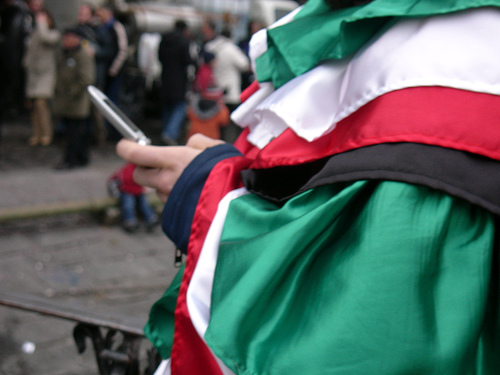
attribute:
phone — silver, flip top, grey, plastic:
[87, 84, 154, 145]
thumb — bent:
[184, 132, 227, 151]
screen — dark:
[103, 97, 140, 133]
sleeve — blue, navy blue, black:
[162, 141, 244, 255]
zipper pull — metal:
[174, 246, 183, 268]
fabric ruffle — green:
[255, 1, 500, 90]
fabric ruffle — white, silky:
[229, 4, 500, 149]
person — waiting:
[108, 159, 160, 235]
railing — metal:
[0, 291, 163, 374]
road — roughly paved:
[1, 218, 187, 374]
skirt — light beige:
[26, 66, 57, 97]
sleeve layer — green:
[203, 180, 499, 374]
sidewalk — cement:
[1, 109, 172, 210]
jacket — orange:
[187, 97, 230, 141]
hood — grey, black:
[193, 96, 219, 121]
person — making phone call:
[116, 1, 500, 374]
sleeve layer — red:
[171, 156, 257, 373]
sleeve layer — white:
[186, 184, 254, 374]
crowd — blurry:
[1, 1, 268, 173]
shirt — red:
[108, 163, 144, 194]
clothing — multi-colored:
[143, 1, 500, 373]